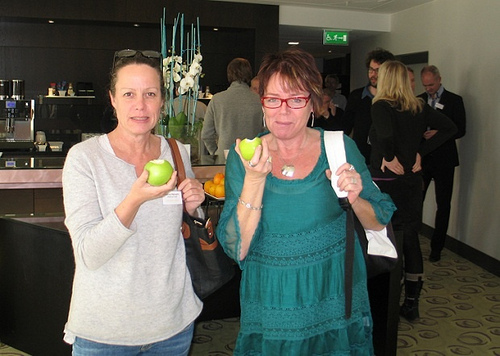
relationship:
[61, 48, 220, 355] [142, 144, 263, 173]
lady eating apples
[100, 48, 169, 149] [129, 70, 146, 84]
lady has light skin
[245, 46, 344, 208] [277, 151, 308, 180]
woman wearing necklace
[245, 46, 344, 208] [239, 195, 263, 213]
woman wearing wristband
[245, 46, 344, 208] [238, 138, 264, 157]
woman eating apple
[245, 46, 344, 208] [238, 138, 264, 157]
woman holding apple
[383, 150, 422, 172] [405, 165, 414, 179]
hands on hips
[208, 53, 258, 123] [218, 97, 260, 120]
man wearing a sweater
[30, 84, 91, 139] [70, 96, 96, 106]
coffee maker has buttons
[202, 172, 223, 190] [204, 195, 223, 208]
oranges in a bowl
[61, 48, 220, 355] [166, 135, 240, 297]
lady holding bag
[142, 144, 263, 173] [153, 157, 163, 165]
apples have bites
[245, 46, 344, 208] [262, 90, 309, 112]
woman has glasses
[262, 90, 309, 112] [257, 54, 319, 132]
glasses on head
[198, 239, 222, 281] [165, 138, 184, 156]
bag on shoulder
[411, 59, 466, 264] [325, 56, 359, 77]
man are standing in hall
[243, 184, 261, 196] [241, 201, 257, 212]
wrist has a bracelet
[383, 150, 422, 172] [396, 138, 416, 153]
hands on back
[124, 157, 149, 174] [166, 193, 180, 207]
chest has tag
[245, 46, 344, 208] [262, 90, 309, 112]
woman with glasses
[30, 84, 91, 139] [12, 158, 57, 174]
coffee maker on top of counter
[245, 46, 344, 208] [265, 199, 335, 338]
woman wearing a dress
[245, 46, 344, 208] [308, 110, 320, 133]
woman wearing earrings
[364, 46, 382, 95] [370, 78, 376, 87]
man with beard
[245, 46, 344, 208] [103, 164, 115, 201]
woman dressed in white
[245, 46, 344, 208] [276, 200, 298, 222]
woman dressed in green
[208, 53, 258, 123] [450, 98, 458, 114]
man in black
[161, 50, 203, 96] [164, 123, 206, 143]
flowers in a pot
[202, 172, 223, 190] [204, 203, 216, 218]
oranges in a basket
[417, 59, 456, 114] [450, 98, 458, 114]
man in black